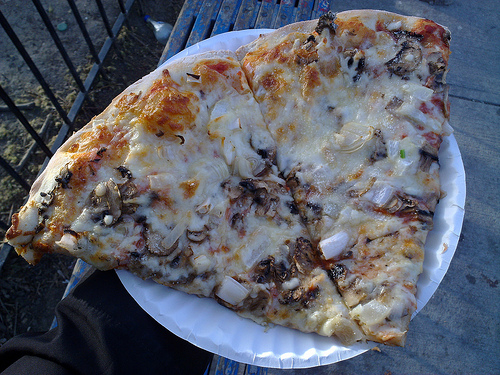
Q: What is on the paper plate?
A: Two pieces of the pizza.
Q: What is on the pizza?
A: Cheese.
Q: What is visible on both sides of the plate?
A: Part of the blue bench.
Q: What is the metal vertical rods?
A: Railing.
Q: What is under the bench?
A: Cemented floor.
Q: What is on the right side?
A: One triangular piece of pizza.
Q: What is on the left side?
A: One triangular piece of pizza.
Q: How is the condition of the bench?
A: Paint peeling off.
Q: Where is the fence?
A: On the left.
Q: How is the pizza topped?
A: Mushroom.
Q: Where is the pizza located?
A: White plate.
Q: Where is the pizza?
A: On a plate.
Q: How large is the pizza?
A: Larger than the plate.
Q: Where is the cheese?
A: On pizza.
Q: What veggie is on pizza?
A: Onions.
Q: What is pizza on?
A: White plate.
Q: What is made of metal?
A: The fence.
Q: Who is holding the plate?
A: The person.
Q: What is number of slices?
A: Two.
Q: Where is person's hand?
A: Under plate.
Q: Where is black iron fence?
A: To left of food.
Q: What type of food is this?
A: Pizza.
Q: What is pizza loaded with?
A: Cheese.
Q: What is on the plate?
A: Pizza.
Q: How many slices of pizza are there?
A: Two.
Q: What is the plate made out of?
A: Paper.